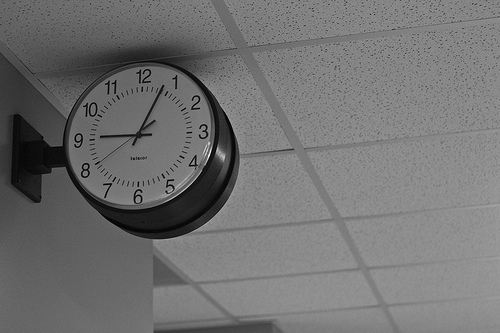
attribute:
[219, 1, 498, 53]
tile — ceiling tile, speckled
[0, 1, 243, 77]
tile — ceiling tile, speckled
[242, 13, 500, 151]
tile — ceiling tile, speckled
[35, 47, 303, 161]
tile — ceiling tile, speckled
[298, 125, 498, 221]
tile — ceiling tile, speckled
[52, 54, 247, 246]
clock — black, hanging, mounted, analog style, white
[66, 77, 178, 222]
clock — 9:04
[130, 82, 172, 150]
hand — minute hand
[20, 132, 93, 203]
support — metal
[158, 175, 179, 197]
symbol — number five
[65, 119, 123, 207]
markings — black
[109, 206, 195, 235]
metal — black